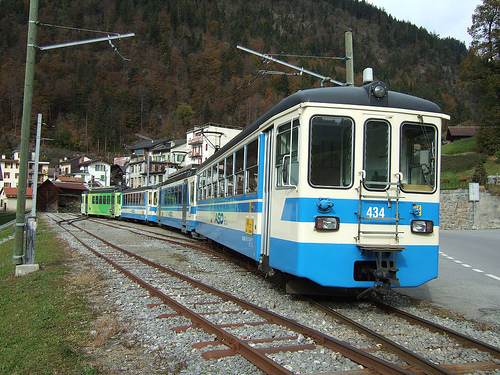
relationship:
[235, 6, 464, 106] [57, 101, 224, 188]
mountains behind houses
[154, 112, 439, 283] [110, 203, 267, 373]
train on train tracks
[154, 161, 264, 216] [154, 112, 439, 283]
windows on train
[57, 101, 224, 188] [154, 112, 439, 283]
houses behind train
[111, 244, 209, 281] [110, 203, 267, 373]
gravels on train tracks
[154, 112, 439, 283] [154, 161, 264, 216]
train has windows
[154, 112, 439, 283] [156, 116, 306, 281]
train has doors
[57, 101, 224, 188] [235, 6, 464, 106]
houses under mountains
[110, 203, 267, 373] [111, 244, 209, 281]
train tracks has gravels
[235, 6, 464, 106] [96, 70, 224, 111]
mountains has trees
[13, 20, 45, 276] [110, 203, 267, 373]
post beside train tracks